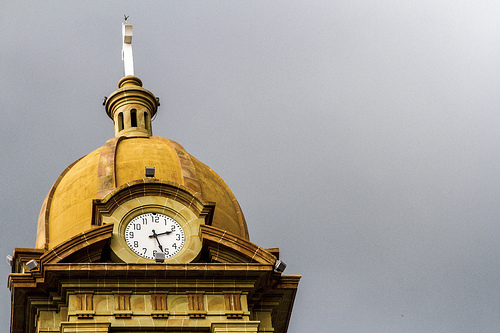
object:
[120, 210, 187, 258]
white-clock face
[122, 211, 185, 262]
clock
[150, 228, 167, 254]
black arrows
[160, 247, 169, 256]
black numbers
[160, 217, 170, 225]
numbers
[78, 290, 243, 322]
columns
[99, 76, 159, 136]
top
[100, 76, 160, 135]
room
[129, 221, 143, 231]
number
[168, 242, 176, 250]
number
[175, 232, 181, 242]
number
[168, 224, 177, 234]
number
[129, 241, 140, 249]
number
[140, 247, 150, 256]
number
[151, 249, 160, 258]
number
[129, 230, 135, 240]
number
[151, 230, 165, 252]
minute hand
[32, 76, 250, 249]
dome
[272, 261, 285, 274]
light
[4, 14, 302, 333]
building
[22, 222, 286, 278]
arch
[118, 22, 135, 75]
cross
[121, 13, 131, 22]
bird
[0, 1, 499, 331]
sky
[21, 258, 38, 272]
light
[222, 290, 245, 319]
stonework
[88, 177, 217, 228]
arch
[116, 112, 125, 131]
window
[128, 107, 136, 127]
window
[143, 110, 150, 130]
window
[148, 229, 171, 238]
hour hand